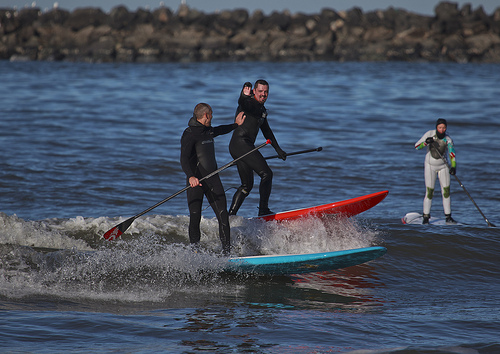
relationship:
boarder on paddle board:
[227, 79, 288, 218] [248, 190, 387, 225]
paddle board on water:
[248, 190, 387, 225] [26, 81, 117, 155]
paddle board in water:
[248, 190, 387, 225] [26, 81, 117, 155]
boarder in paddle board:
[227, 79, 288, 218] [248, 190, 387, 225]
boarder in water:
[227, 79, 288, 218] [26, 81, 117, 155]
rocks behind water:
[205, 7, 290, 47] [26, 81, 117, 155]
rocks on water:
[205, 7, 290, 47] [26, 81, 117, 155]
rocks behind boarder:
[205, 7, 290, 47] [227, 79, 288, 218]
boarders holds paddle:
[179, 102, 245, 258] [97, 162, 251, 251]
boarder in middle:
[221, 71, 288, 225] [232, 24, 275, 273]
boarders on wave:
[179, 102, 245, 258] [8, 204, 498, 313]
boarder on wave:
[227, 79, 288, 218] [8, 204, 498, 313]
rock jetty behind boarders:
[4, 4, 498, 74] [173, 73, 463, 253]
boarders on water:
[170, 69, 462, 236] [4, 245, 496, 348]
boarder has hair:
[227, 79, 288, 218] [182, 96, 211, 121]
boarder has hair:
[227, 79, 288, 218] [252, 71, 268, 89]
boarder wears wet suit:
[227, 79, 288, 218] [228, 83, 288, 214]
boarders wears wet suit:
[179, 102, 245, 258] [179, 118, 240, 254]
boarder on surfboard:
[227, 79, 288, 218] [273, 180, 393, 225]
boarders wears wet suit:
[179, 102, 245, 258] [228, 99, 289, 219]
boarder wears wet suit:
[227, 79, 288, 218] [170, 126, 244, 240]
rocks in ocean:
[10, 8, 499, 66] [1, 70, 495, 340]